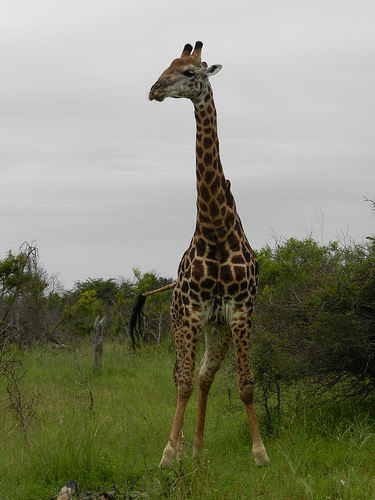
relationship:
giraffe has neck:
[159, 25, 275, 476] [190, 108, 224, 146]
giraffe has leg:
[159, 25, 275, 476] [233, 340, 261, 455]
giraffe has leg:
[159, 25, 275, 476] [186, 324, 228, 467]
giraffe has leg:
[159, 25, 275, 476] [178, 349, 191, 464]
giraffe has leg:
[159, 25, 275, 476] [172, 370, 177, 381]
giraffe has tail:
[159, 25, 275, 476] [141, 288, 172, 300]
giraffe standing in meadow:
[159, 25, 275, 476] [34, 314, 365, 499]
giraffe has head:
[159, 25, 275, 476] [153, 57, 184, 97]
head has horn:
[153, 57, 184, 97] [197, 42, 200, 55]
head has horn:
[153, 57, 184, 97] [184, 45, 189, 51]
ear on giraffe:
[205, 62, 230, 79] [159, 25, 275, 476]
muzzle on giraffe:
[154, 84, 169, 95] [159, 25, 275, 476]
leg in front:
[233, 340, 261, 455] [202, 277, 231, 295]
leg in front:
[178, 349, 191, 464] [202, 277, 231, 295]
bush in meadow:
[309, 318, 359, 379] [34, 314, 365, 499]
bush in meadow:
[265, 260, 312, 284] [34, 314, 365, 499]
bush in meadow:
[71, 291, 100, 343] [34, 314, 365, 499]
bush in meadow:
[75, 301, 99, 315] [34, 314, 365, 499]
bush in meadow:
[15, 281, 38, 308] [34, 314, 365, 499]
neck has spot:
[190, 108, 224, 146] [205, 138, 214, 148]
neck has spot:
[190, 108, 224, 146] [208, 110, 210, 113]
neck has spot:
[190, 108, 224, 146] [192, 107, 200, 110]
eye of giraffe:
[187, 66, 198, 79] [159, 25, 275, 476]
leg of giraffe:
[186, 324, 228, 467] [138, 33, 273, 480]